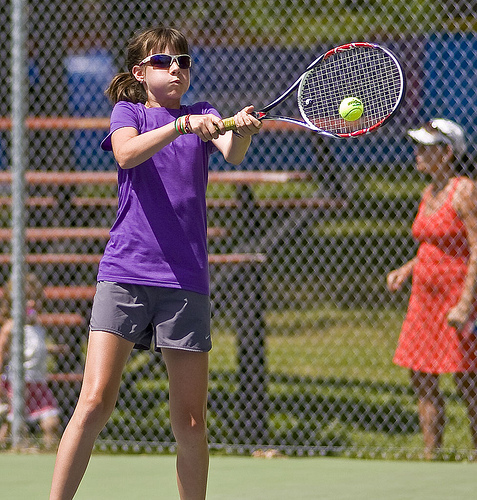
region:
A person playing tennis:
[45, 19, 411, 498]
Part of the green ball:
[345, 103, 355, 111]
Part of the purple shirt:
[152, 200, 192, 235]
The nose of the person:
[170, 56, 181, 75]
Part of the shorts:
[109, 291, 127, 312]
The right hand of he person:
[187, 110, 227, 144]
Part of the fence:
[11, 199, 38, 258]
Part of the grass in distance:
[315, 352, 347, 372]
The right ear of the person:
[130, 60, 147, 81]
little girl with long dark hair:
[72, 24, 222, 115]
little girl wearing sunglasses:
[85, 19, 256, 119]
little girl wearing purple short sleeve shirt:
[67, 68, 253, 322]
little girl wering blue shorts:
[45, 235, 255, 374]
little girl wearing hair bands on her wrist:
[108, 88, 253, 174]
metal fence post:
[0, 6, 48, 337]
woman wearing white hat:
[394, 100, 466, 204]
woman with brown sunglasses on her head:
[394, 103, 473, 209]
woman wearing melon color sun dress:
[393, 167, 468, 383]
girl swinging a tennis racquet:
[93, 31, 424, 180]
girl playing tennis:
[54, 27, 404, 490]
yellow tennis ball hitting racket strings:
[327, 91, 368, 120]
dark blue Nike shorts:
[90, 275, 215, 357]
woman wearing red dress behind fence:
[392, 112, 470, 453]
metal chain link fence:
[8, 9, 459, 464]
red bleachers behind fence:
[6, 166, 302, 422]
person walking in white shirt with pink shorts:
[4, 265, 59, 440]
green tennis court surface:
[24, 456, 467, 496]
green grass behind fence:
[287, 342, 390, 444]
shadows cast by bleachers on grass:
[135, 377, 399, 440]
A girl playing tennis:
[37, 24, 408, 498]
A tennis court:
[5, 447, 475, 493]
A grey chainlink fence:
[0, 1, 475, 463]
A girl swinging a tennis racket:
[9, 26, 406, 496]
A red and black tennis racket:
[195, 41, 406, 147]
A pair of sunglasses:
[125, 51, 195, 72]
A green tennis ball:
[332, 85, 366, 123]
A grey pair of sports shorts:
[91, 276, 212, 349]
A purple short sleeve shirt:
[110, 77, 222, 294]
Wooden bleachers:
[1, 103, 368, 448]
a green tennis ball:
[337, 94, 363, 119]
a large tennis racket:
[222, 41, 406, 163]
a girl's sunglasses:
[128, 50, 197, 76]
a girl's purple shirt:
[98, 97, 232, 293]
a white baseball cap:
[406, 120, 466, 152]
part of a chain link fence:
[2, 0, 474, 454]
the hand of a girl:
[186, 108, 223, 142]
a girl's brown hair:
[99, 27, 191, 108]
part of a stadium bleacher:
[6, 114, 368, 417]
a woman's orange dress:
[387, 173, 475, 372]